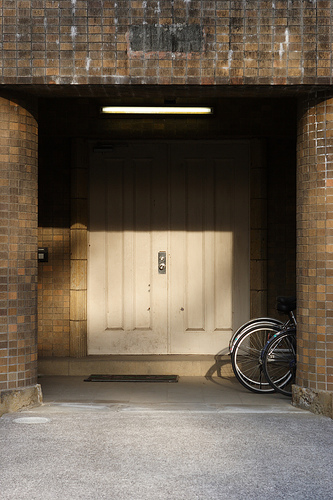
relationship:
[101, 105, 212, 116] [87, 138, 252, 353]
light over door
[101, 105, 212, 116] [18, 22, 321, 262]
light in front of house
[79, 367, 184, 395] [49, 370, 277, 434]
doormat on ground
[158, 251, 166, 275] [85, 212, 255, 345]
doorknob on door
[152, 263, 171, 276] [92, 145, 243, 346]
doorknob on door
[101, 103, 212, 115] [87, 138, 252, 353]
light in front of door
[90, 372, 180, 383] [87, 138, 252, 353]
doormat in front of door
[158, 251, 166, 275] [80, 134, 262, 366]
doorknob on door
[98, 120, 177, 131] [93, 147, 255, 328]
object on top door